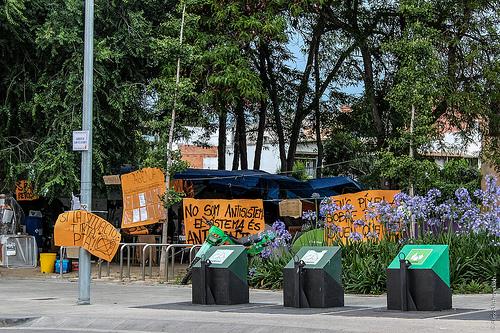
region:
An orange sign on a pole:
[52, 211, 121, 261]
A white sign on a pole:
[65, 128, 92, 152]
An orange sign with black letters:
[177, 195, 263, 237]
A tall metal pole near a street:
[72, 0, 97, 301]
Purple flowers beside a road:
[362, 176, 498, 235]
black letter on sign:
[183, 204, 194, 217]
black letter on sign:
[191, 205, 200, 218]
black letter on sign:
[201, 201, 213, 218]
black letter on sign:
[211, 203, 222, 215]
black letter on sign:
[223, 203, 231, 218]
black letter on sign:
[193, 218, 201, 227]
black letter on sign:
[198, 218, 205, 229]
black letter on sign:
[186, 228, 192, 243]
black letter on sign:
[190, 230, 201, 245]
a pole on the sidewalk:
[59, 0, 149, 318]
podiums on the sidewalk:
[178, 225, 468, 327]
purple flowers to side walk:
[229, 165, 494, 268]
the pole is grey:
[62, 11, 127, 311]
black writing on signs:
[169, 171, 396, 271]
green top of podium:
[385, 236, 461, 288]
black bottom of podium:
[385, 253, 447, 310]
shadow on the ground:
[163, 301, 198, 312]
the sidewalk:
[103, 279, 132, 301]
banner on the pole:
[59, 215, 114, 256]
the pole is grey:
[81, 159, 89, 203]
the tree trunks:
[218, 115, 263, 170]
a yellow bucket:
[36, 250, 58, 272]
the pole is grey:
[118, 247, 135, 279]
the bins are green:
[195, 238, 438, 315]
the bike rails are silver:
[95, 239, 205, 290]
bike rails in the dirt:
[99, 237, 209, 274]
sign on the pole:
[52, 197, 125, 304]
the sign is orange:
[57, 203, 121, 260]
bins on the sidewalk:
[192, 241, 455, 328]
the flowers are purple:
[299, 199, 491, 246]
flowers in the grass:
[322, 192, 499, 284]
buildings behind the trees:
[200, 114, 493, 181]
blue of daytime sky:
[140, 0, 497, 125]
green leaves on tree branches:
[1, 2, 498, 194]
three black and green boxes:
[192, 242, 451, 302]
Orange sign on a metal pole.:
[49, 208, 117, 260]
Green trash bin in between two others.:
[283, 245, 343, 305]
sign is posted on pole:
[51, 210, 122, 257]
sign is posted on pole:
[71, 127, 91, 149]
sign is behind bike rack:
[119, 162, 167, 232]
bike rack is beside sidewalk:
[57, 235, 202, 284]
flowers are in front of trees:
[250, 175, 498, 291]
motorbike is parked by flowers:
[181, 215, 278, 285]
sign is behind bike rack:
[184, 198, 266, 245]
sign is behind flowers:
[325, 190, 400, 242]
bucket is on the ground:
[36, 252, 56, 272]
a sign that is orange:
[174, 186, 264, 246]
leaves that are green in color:
[97, 22, 184, 129]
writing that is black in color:
[61, 213, 98, 247]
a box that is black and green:
[397, 241, 442, 301]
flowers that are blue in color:
[424, 182, 475, 233]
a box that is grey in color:
[1, 225, 41, 273]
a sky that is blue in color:
[272, 29, 309, 80]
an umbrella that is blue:
[197, 162, 327, 203]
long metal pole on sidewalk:
[71, 0, 104, 310]